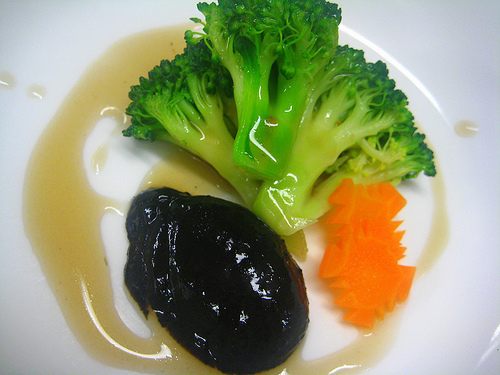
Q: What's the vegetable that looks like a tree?
A: Broccoli.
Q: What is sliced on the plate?
A: A bright orange carrot.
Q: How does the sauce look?
A: The sauce is light brown in color.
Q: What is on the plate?
A: A few pieces od broccoli.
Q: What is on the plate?
A: A cooked green vegetable.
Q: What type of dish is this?
A: A simple vegetarian dish.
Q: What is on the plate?
A: Vegetables are on the plate.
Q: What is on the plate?
A: A black shell.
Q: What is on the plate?
A: A mound of green broccoli.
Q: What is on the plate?
A: A vegetarian meal is on the plate.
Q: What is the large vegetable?
A: Brocooli.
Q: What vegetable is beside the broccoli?
A: A carrot.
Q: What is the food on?
A: A plate.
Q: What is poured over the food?
A: A sauce.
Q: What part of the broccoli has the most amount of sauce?
A: The stem.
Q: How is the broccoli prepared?
A: Cooked.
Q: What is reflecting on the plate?
A: The light.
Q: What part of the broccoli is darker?
A: The floret.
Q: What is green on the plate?
A: Broccoli.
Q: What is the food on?
A: A plate.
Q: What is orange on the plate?
A: Carrot.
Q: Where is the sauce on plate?
A: On the left.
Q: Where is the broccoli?
A: On a plate.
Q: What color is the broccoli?
A: Green.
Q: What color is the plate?
A: White.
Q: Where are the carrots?
A: On the plate.